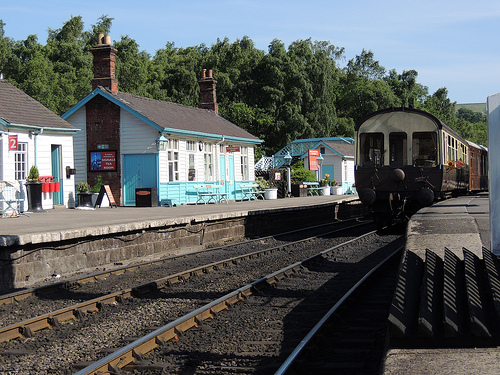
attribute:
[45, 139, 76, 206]
door — blue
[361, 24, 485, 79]
sky — clear, blue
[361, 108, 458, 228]
train — white, black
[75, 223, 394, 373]
gravel — black, gray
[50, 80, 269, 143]
roof — black, tiled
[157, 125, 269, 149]
edge — blue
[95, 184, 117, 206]
sign — white, red, small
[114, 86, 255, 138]
roof — sloped, grey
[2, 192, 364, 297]
platform — gray, cement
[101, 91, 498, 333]
station — train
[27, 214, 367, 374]
train tracks — brown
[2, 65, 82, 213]
building — blue, white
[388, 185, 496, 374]
platform — black, gray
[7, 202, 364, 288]
wall — grey, cinderblock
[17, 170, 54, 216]
pot — black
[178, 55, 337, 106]
leaves — green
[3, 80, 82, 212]
house — white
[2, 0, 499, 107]
sky — blue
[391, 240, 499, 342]
ridges — raised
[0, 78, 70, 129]
roof — black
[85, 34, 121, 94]
chimney — brown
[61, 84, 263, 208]
building — white